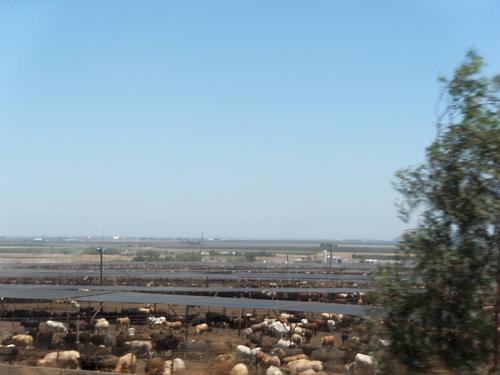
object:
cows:
[318, 334, 336, 353]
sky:
[1, 3, 499, 245]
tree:
[373, 47, 499, 371]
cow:
[45, 319, 70, 338]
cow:
[144, 356, 161, 375]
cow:
[155, 334, 181, 354]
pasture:
[4, 247, 497, 375]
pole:
[96, 248, 104, 283]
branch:
[404, 170, 434, 202]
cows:
[193, 322, 212, 338]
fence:
[0, 307, 382, 374]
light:
[95, 247, 104, 254]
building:
[322, 248, 346, 268]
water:
[10, 292, 392, 320]